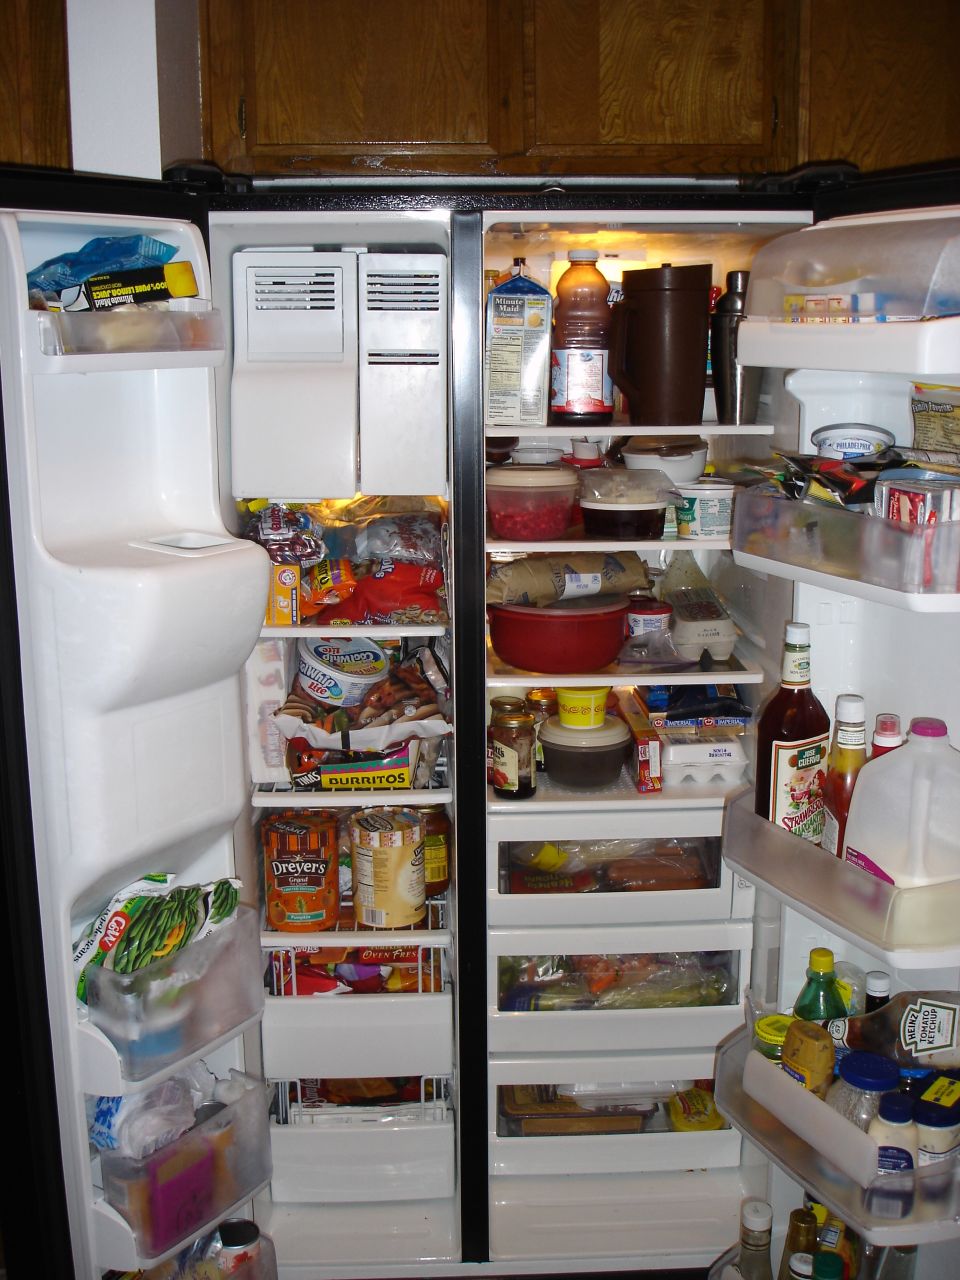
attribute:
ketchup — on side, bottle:
[796, 986, 957, 1082]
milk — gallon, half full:
[833, 702, 955, 946]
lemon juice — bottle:
[795, 942, 851, 1048]